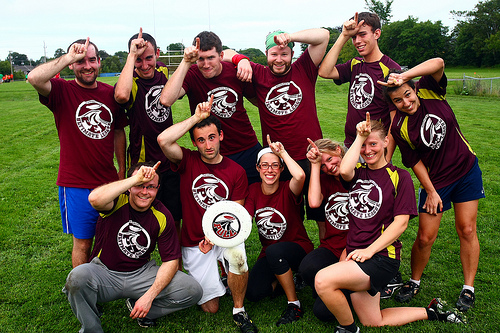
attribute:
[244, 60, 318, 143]
shirt — burgundy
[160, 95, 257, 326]
man — holding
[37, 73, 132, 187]
shirt — red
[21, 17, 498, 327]
players — team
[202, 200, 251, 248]
frisbee — white, plastic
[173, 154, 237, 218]
logo — white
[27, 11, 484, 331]
team — posing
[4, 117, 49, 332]
grass — green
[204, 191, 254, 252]
frisbee — white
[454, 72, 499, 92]
fence — chain link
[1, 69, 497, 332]
grass — short, green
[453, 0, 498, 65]
tree — green, large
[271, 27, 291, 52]
hand — signing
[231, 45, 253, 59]
wristband — red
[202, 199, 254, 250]
frisbee — white, red, black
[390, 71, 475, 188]
shirt — burgundy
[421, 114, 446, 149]
logo — white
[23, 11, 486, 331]
group — people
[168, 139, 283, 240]
shirt — maroon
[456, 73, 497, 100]
gate — metal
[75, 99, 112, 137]
logo — white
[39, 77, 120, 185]
shirt — burgundy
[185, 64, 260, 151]
t-shirt — burgundy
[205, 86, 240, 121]
logo — white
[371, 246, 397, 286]
shorts — black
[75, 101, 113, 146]
logo — white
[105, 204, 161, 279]
t-shirt — burgundy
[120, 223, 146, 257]
logo — white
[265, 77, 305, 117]
logo — white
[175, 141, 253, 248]
t-shirt — burgundy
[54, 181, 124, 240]
shorts — blue